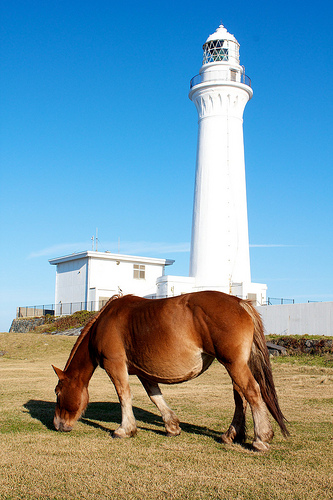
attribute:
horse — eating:
[54, 291, 301, 442]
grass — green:
[6, 417, 145, 453]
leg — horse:
[227, 354, 276, 453]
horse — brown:
[52, 293, 308, 477]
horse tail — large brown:
[240, 300, 295, 439]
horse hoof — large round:
[106, 426, 148, 438]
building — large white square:
[45, 243, 173, 303]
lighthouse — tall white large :
[182, 18, 264, 288]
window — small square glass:
[131, 263, 148, 277]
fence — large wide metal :
[20, 300, 315, 335]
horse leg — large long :
[235, 360, 276, 459]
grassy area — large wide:
[2, 412, 59, 470]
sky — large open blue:
[17, 53, 162, 211]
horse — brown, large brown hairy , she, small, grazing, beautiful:
[49, 288, 299, 455]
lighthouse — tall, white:
[155, 16, 271, 302]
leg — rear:
[225, 358, 277, 454]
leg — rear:
[222, 384, 248, 449]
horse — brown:
[43, 285, 291, 461]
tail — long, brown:
[249, 299, 293, 441]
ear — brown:
[49, 362, 66, 381]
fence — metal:
[14, 292, 331, 320]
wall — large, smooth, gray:
[253, 300, 330, 341]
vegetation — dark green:
[273, 352, 330, 366]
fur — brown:
[110, 298, 198, 364]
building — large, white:
[44, 249, 176, 318]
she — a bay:
[49, 290, 292, 454]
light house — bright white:
[185, 21, 261, 285]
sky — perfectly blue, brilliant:
[3, 2, 187, 164]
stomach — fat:
[125, 330, 220, 385]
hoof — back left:
[252, 421, 275, 451]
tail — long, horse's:
[235, 297, 294, 440]